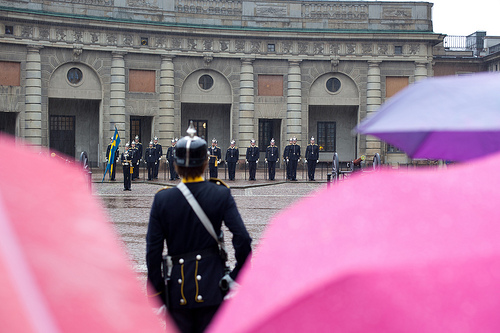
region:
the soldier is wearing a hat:
[175, 129, 207, 169]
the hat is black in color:
[173, 133, 208, 165]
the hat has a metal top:
[183, 124, 200, 141]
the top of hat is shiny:
[181, 128, 199, 140]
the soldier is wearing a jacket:
[150, 179, 251, 284]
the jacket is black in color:
[148, 183, 252, 275]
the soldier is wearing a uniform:
[144, 182, 254, 332]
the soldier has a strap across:
[178, 181, 221, 250]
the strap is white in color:
[177, 180, 223, 256]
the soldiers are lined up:
[103, 131, 335, 178]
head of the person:
[165, 121, 228, 188]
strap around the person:
[175, 180, 225, 240]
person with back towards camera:
[115, 111, 260, 251]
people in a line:
[230, 130, 325, 166]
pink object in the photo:
[285, 180, 400, 271]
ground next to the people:
[110, 188, 148, 226]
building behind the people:
[153, 46, 258, 111]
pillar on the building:
[235, 55, 260, 131]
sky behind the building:
[445, 3, 480, 25]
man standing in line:
[299, 120, 332, 180]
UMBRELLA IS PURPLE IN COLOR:
[357, 82, 498, 154]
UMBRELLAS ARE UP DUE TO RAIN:
[1, 73, 498, 325]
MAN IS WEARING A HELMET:
[167, 118, 217, 183]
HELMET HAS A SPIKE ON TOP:
[179, 113, 204, 140]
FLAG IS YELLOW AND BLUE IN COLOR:
[99, 122, 121, 185]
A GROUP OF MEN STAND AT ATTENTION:
[106, 136, 323, 179]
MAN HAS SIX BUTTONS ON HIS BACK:
[173, 251, 210, 307]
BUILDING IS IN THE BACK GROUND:
[0, 3, 438, 179]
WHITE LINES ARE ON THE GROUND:
[79, 180, 335, 200]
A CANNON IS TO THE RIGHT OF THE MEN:
[329, 149, 394, 174]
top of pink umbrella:
[311, 183, 471, 263]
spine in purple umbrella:
[351, 79, 428, 119]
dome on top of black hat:
[178, 118, 212, 143]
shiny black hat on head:
[154, 114, 233, 185]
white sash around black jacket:
[166, 180, 238, 245]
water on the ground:
[103, 186, 147, 215]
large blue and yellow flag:
[93, 126, 124, 179]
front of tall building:
[62, 13, 354, 135]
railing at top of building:
[433, 27, 474, 49]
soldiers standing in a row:
[125, 124, 331, 178]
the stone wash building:
[0, 5, 495, 165]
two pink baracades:
[0, 136, 492, 331]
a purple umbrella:
[346, 63, 498, 162]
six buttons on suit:
[171, 254, 208, 305]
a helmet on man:
[167, 124, 209, 174]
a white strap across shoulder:
[174, 179, 226, 253]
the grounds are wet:
[93, 156, 395, 288]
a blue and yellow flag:
[103, 123, 123, 175]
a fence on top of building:
[435, 26, 497, 53]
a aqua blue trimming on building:
[1, 5, 434, 41]